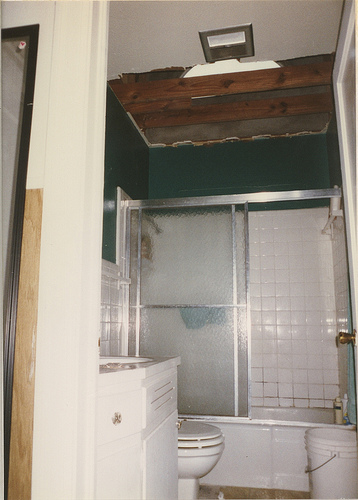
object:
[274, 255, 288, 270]
tiles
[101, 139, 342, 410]
wall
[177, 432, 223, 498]
toilet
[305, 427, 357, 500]
bucket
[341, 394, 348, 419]
products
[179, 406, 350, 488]
bathtub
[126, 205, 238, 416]
doors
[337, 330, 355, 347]
doorknob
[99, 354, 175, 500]
sink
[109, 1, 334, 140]
ceiling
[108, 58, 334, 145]
hole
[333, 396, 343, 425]
shampoo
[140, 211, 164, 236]
showerhead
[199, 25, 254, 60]
vent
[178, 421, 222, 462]
seat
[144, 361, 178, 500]
cabinets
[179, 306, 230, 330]
towel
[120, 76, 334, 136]
wood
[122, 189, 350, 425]
shower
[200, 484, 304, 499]
floor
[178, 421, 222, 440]
lid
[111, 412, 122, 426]
knobs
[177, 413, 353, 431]
ledge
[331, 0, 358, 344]
frame